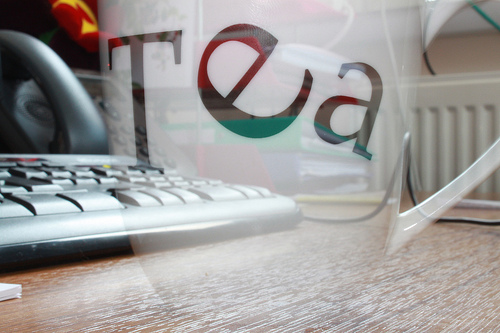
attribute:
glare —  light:
[95, 10, 494, 313]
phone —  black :
[4, 25, 206, 181]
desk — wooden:
[0, 203, 497, 329]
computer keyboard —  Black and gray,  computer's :
[3, 142, 323, 283]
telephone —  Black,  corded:
[4, 25, 131, 182]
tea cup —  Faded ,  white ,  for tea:
[87, 0, 497, 314]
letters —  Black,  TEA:
[106, 22, 384, 187]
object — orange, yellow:
[51, 0, 118, 49]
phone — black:
[1, 30, 114, 154]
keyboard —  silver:
[0, 148, 317, 274]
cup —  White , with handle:
[393, 36, 497, 292]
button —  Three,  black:
[54, 192, 124, 210]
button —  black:
[9, 193, 81, 215]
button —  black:
[1, 195, 32, 218]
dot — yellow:
[96, 159, 116, 178]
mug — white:
[132, 48, 385, 189]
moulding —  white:
[203, 1, 490, 83]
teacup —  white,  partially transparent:
[98, 0, 499, 322]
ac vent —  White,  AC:
[402, 69, 497, 215]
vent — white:
[404, 75, 498, 223]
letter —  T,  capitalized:
[93, 25, 198, 187]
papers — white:
[1, 284, 22, 303]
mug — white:
[94, 3, 497, 287]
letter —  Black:
[105, 26, 182, 174]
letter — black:
[197, 21, 312, 138]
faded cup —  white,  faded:
[99, 0, 424, 332]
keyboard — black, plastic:
[0, 153, 302, 266]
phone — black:
[25, 30, 165, 175]